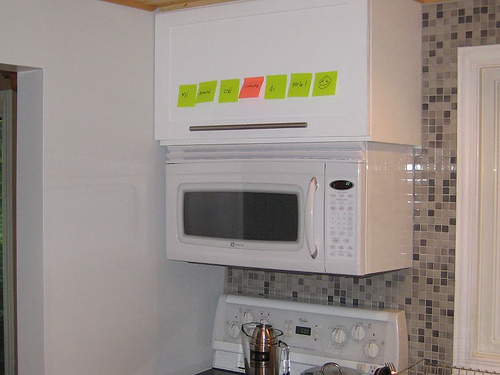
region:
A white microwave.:
[148, 141, 421, 283]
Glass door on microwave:
[168, 174, 308, 261]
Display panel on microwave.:
[322, 172, 359, 192]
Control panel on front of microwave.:
[320, 187, 364, 266]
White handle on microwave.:
[296, 170, 323, 262]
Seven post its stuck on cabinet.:
[169, 62, 349, 110]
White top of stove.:
[206, 282, 421, 373]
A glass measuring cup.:
[236, 315, 288, 372]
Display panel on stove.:
[285, 316, 320, 339]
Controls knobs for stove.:
[216, 288, 391, 366]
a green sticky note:
[311, 71, 339, 93]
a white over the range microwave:
[157, 143, 412, 277]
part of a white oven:
[192, 289, 405, 374]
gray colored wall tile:
[418, 0, 494, 42]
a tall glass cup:
[230, 317, 295, 373]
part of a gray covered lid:
[297, 360, 363, 374]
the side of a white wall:
[0, 1, 222, 373]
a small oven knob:
[350, 325, 365, 341]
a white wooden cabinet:
[149, 0, 428, 143]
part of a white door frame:
[0, 87, 14, 374]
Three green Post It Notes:
[176, 83, 236, 105]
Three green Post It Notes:
[264, 72, 335, 98]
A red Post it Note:
[239, 75, 263, 101]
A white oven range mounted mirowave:
[161, 151, 413, 277]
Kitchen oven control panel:
[213, 293, 406, 370]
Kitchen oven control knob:
[328, 325, 348, 345]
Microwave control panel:
[326, 160, 360, 273]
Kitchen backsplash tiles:
[423, 4, 451, 365]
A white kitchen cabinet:
[156, 2, 423, 145]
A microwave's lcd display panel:
[329, 177, 355, 190]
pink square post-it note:
[236, 73, 264, 100]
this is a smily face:
[313, 64, 343, 95]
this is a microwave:
[141, 129, 441, 292]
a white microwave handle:
[292, 171, 330, 273]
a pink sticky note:
[234, 72, 269, 104]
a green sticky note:
[279, 70, 323, 106]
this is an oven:
[163, 277, 416, 373]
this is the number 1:
[329, 209, 337, 216]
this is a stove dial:
[328, 322, 353, 352]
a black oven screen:
[291, 322, 316, 338]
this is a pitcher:
[233, 314, 297, 372]